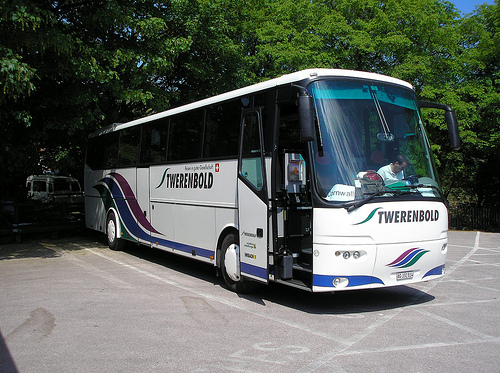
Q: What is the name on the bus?
A: Twerenbold.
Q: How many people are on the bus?
A: 10.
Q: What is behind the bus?
A: A Van.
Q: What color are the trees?
A: Green.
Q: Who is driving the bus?
A: A man.